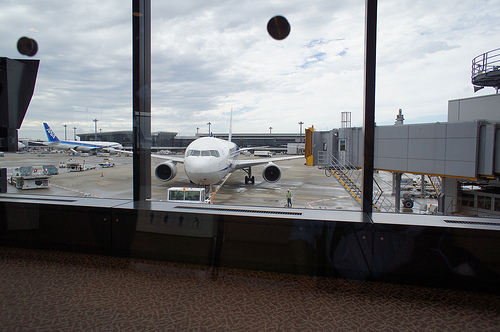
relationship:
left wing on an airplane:
[236, 155, 304, 168] [121, 135, 281, 186]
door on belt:
[295, 114, 335, 196] [298, 127, 318, 166]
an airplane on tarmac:
[121, 135, 281, 186] [4, 148, 394, 208]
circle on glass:
[267, 15, 289, 38] [149, 0, 363, 203]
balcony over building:
[465, 40, 484, 97] [248, 131, 293, 149]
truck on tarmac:
[67, 138, 139, 182] [12, 147, 392, 207]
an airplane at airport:
[121, 135, 281, 186] [100, 135, 303, 184]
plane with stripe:
[37, 122, 123, 155] [52, 140, 103, 150]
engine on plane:
[258, 156, 296, 183] [52, 113, 331, 203]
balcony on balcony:
[469, 49, 498, 88] [469, 49, 498, 88]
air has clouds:
[0, 0, 479, 119] [119, 33, 283, 120]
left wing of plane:
[236, 155, 304, 168] [112, 111, 305, 187]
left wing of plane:
[238, 152, 311, 170] [101, 132, 304, 187]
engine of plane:
[154, 161, 178, 182] [102, 136, 305, 189]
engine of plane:
[154, 161, 178, 182] [145, 129, 312, 199]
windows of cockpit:
[185, 149, 219, 158] [176, 132, 234, 181]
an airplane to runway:
[121, 135, 281, 186] [225, 130, 312, 187]